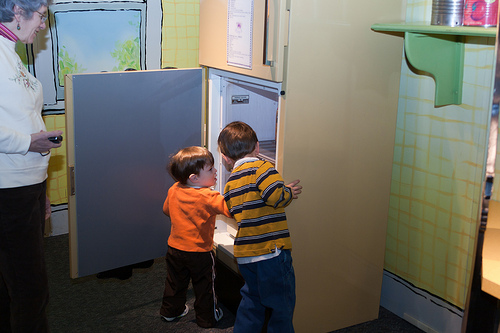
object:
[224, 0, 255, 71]
paper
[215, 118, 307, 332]
boy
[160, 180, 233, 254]
shirt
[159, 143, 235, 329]
boy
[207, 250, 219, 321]
stripe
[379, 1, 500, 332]
wall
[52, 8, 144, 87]
fake window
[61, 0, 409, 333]
fridge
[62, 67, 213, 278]
door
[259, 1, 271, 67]
handle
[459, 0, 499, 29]
can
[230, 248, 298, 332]
jeans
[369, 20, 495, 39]
shelf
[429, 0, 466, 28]
canister